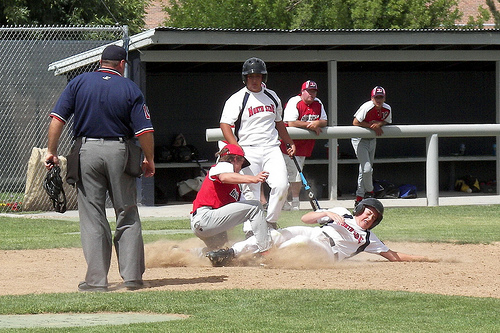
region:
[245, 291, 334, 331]
this is the grass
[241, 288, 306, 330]
the grass is green in color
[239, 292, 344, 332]
the grass is short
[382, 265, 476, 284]
this is the ground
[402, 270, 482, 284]
the ground is sandy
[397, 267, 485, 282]
the sand is brown in color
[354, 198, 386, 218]
this is a helmet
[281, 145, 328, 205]
this is a bat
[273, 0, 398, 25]
these are some trees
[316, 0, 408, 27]
the leaves are green in color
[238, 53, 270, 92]
Helmet being worn by baseball player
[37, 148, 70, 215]
black plastic bag held by man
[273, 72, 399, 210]
Two baseball players watching the game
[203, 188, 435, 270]
Baseball player sliding in the dirt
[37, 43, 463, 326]
Baseball game being played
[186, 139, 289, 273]
Baseball player with a white and red uniform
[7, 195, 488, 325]
Well-mowed baseball playing field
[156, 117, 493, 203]
Bags and equipment stored in the sidelines of field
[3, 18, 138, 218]
Tall metal fence around playing field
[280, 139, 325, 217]
Black, blue and white baseball bat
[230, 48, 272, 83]
batter has black helmet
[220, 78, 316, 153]
batter has white shirt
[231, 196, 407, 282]
player is sliding into home plate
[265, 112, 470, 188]
dugout has white rail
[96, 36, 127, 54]
umpire has blue cap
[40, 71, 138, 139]
umpire has blue shirt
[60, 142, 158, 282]
umpire has grey pants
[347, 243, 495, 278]
dirt is light brown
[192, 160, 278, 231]
catcher has red shirt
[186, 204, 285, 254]
catcher has grey pants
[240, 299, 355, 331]
The grass is green.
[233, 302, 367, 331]
The grass is short.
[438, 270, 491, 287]
The dirt is brown.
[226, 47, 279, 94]
The person is wearing a helmet.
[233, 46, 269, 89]
The helmet is black.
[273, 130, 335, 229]
The person is holding a bat.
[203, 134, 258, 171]
The person is wearing a hat.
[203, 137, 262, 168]
The hat is red.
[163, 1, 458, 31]
The trees are green.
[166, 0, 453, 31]
Trees are in the background.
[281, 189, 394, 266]
a baseball player sliding into home base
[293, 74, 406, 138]
players on the sidelines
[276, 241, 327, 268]
dust swirling in the air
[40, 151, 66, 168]
a hand holding a black mask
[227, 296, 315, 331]
green grass around the base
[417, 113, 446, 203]
a white metal fence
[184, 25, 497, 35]
the corrugated edge of a roof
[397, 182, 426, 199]
a blue bag on the ground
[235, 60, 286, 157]
a player holding a black bat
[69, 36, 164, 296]
a man wearing gray pants